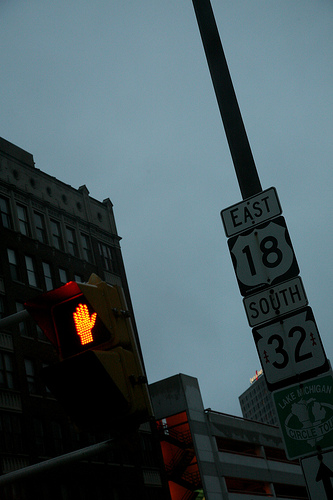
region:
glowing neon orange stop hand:
[69, 299, 101, 349]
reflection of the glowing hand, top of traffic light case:
[36, 278, 98, 307]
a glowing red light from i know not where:
[150, 408, 287, 498]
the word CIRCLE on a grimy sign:
[284, 424, 319, 440]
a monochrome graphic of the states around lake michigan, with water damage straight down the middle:
[286, 392, 331, 447]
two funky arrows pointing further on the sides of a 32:
[258, 326, 320, 371]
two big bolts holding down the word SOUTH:
[268, 286, 283, 316]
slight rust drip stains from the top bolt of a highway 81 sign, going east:
[252, 229, 260, 245]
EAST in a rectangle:
[206, 187, 286, 240]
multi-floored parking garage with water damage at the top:
[146, 371, 308, 498]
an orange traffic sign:
[30, 271, 148, 493]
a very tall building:
[0, 136, 171, 499]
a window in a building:
[20, 254, 37, 288]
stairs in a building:
[156, 412, 200, 496]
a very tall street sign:
[212, 178, 331, 497]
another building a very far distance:
[238, 366, 278, 416]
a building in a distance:
[146, 370, 304, 499]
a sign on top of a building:
[247, 368, 263, 382]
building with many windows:
[237, 373, 277, 424]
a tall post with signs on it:
[190, 0, 330, 498]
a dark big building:
[0, 135, 331, 495]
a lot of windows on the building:
[2, 152, 300, 499]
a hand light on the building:
[71, 301, 99, 348]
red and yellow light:
[0, 271, 155, 482]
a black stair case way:
[156, 409, 204, 497]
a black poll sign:
[172, 0, 330, 498]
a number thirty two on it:
[248, 307, 330, 392]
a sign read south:
[231, 276, 311, 332]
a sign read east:
[217, 184, 281, 238]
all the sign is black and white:
[215, 184, 330, 390]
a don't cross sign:
[26, 297, 124, 352]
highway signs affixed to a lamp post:
[221, 209, 326, 382]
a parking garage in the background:
[168, 380, 289, 492]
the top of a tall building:
[3, 140, 130, 288]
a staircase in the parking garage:
[156, 417, 202, 498]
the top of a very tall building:
[238, 371, 268, 418]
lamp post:
[182, 0, 264, 191]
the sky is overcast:
[116, 3, 188, 352]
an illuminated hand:
[62, 303, 103, 349]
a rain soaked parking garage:
[146, 379, 278, 497]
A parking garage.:
[148, 378, 303, 497]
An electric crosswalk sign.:
[40, 281, 158, 443]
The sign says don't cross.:
[38, 283, 118, 344]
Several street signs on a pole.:
[210, 177, 328, 465]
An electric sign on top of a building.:
[231, 361, 261, 396]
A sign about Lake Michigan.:
[265, 370, 327, 453]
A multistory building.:
[0, 133, 166, 494]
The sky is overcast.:
[115, 116, 224, 252]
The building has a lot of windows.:
[1, 181, 124, 361]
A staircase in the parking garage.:
[157, 406, 196, 497]